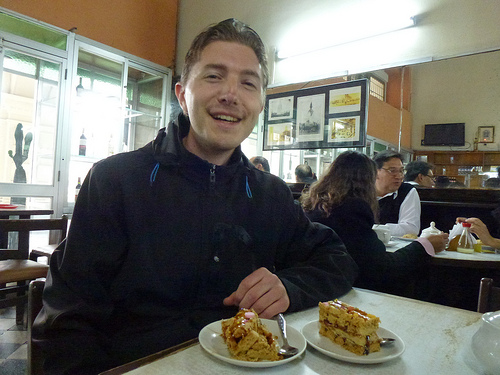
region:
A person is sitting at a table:
[12, 10, 489, 371]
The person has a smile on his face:
[171, 16, 277, 153]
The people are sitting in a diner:
[15, 25, 487, 370]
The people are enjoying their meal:
[21, 8, 496, 309]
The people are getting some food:
[13, 6, 498, 366]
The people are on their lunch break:
[20, 20, 497, 370]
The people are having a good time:
[17, 15, 497, 355]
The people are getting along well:
[10, 10, 497, 355]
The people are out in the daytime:
[40, 18, 490, 360]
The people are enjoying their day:
[35, 18, 475, 367]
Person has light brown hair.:
[197, 14, 271, 36]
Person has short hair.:
[178, 17, 270, 47]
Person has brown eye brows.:
[204, 58, 271, 80]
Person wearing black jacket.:
[136, 198, 231, 240]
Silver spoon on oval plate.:
[268, 310, 298, 364]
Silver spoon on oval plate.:
[375, 319, 399, 348]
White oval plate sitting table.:
[316, 300, 388, 372]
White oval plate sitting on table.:
[216, 321, 288, 370]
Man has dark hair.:
[378, 148, 400, 161]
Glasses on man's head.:
[384, 158, 410, 179]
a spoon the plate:
[271, 308, 295, 362]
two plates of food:
[200, 288, 391, 370]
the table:
[120, 295, 410, 371]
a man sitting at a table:
[62, 27, 347, 363]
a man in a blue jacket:
[72, 30, 339, 365]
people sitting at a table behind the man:
[305, 137, 498, 279]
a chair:
[1, 207, 67, 327]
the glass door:
[6, 16, 162, 221]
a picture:
[268, 88, 360, 150]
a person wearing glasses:
[381, 148, 414, 209]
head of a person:
[163, 11, 283, 156]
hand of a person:
[230, 258, 305, 328]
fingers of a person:
[226, 242, 291, 327]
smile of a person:
[193, 109, 245, 133]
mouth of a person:
[195, 103, 247, 134]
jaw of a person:
[185, 133, 259, 158]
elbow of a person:
[326, 216, 361, 303]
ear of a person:
[160, 81, 200, 116]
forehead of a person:
[189, 45, 269, 77]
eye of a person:
[195, 75, 222, 86]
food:
[321, 300, 379, 355]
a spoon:
[379, 335, 399, 345]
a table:
[398, 310, 440, 342]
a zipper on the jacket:
[206, 167, 216, 187]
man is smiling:
[207, 110, 244, 125]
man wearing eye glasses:
[385, 166, 405, 174]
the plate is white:
[200, 332, 221, 352]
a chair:
[1, 257, 37, 272]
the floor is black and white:
[1, 336, 24, 364]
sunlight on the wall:
[295, 26, 397, 56]